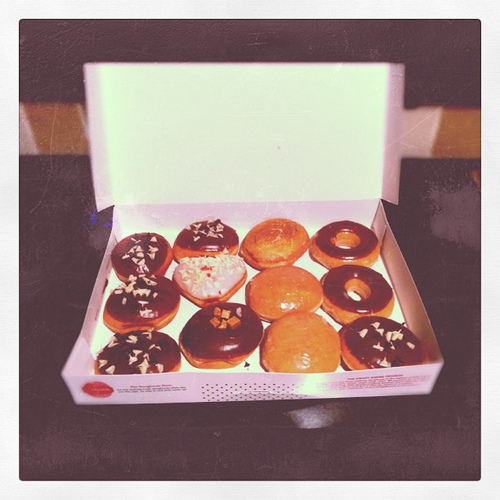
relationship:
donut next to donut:
[311, 218, 381, 267] [242, 211, 320, 270]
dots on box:
[202, 381, 299, 402] [57, 53, 448, 413]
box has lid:
[57, 53, 448, 413] [79, 50, 407, 217]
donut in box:
[103, 229, 173, 281] [57, 53, 448, 413]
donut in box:
[171, 218, 237, 264] [57, 53, 448, 413]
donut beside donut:
[107, 229, 173, 281] [171, 218, 237, 264]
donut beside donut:
[171, 218, 237, 264] [238, 216, 311, 269]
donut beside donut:
[238, 216, 311, 269] [303, 218, 381, 268]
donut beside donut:
[303, 218, 381, 268] [316, 262, 398, 319]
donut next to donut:
[107, 229, 173, 281] [171, 218, 237, 264]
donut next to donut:
[171, 218, 237, 264] [238, 216, 311, 269]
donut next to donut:
[238, 216, 311, 269] [311, 218, 381, 267]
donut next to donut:
[311, 218, 381, 267] [317, 264, 400, 324]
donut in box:
[107, 229, 173, 281] [57, 53, 448, 413]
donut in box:
[238, 216, 311, 269] [57, 53, 448, 413]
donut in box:
[311, 218, 381, 267] [57, 53, 448, 413]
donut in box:
[317, 264, 400, 324] [57, 53, 448, 413]